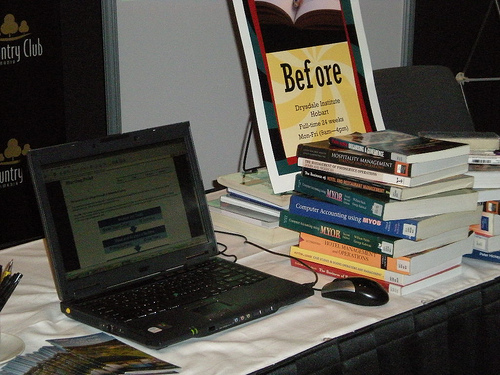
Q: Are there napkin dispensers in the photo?
A: No, there are no napkin dispensers.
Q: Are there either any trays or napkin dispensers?
A: No, there are no napkin dispensers or trays.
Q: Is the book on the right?
A: Yes, the book is on the right of the image.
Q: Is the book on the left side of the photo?
A: No, the book is on the right of the image.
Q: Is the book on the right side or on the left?
A: The book is on the right of the image.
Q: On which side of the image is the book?
A: The book is on the right of the image.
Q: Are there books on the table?
A: Yes, there is a book on the table.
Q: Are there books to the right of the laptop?
A: Yes, there is a book to the right of the laptop.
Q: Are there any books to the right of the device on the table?
A: Yes, there is a book to the right of the laptop.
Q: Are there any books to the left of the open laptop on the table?
A: No, the book is to the right of the laptop.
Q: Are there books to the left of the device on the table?
A: No, the book is to the right of the laptop.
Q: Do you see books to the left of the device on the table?
A: No, the book is to the right of the laptop.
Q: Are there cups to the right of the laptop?
A: No, there is a book to the right of the laptop.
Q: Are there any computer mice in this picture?
A: Yes, there is a computer mouse.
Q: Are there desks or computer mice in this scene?
A: Yes, there is a computer mouse.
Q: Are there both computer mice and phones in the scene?
A: No, there is a computer mouse but no phones.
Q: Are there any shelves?
A: No, there are no shelves.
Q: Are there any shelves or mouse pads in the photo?
A: No, there are no shelves or mouse pads.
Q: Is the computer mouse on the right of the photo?
A: Yes, the computer mouse is on the right of the image.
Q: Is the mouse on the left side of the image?
A: No, the mouse is on the right of the image.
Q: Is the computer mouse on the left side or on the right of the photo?
A: The computer mouse is on the right of the image.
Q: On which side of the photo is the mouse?
A: The mouse is on the right of the image.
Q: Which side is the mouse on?
A: The mouse is on the right of the image.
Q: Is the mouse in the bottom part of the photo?
A: Yes, the mouse is in the bottom of the image.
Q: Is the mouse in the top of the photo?
A: No, the mouse is in the bottom of the image.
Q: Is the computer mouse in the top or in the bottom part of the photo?
A: The computer mouse is in the bottom of the image.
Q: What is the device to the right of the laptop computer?
A: The device is a computer mouse.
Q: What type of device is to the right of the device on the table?
A: The device is a computer mouse.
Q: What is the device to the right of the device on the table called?
A: The device is a computer mouse.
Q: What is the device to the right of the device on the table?
A: The device is a computer mouse.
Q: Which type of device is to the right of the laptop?
A: The device is a computer mouse.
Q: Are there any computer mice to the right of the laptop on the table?
A: Yes, there is a computer mouse to the right of the laptop.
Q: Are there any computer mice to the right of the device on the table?
A: Yes, there is a computer mouse to the right of the laptop.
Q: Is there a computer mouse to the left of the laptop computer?
A: No, the computer mouse is to the right of the laptop computer.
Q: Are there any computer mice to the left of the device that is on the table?
A: No, the computer mouse is to the right of the laptop computer.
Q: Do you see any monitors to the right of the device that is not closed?
A: No, there is a computer mouse to the right of the laptop.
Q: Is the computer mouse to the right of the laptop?
A: Yes, the computer mouse is to the right of the laptop.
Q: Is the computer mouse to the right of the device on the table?
A: Yes, the computer mouse is to the right of the laptop.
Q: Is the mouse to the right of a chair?
A: No, the mouse is to the right of the laptop.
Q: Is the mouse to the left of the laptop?
A: No, the mouse is to the right of the laptop.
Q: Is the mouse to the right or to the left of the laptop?
A: The mouse is to the right of the laptop.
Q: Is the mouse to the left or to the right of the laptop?
A: The mouse is to the right of the laptop.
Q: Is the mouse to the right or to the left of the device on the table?
A: The mouse is to the right of the laptop.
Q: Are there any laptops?
A: Yes, there is a laptop.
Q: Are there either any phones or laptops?
A: Yes, there is a laptop.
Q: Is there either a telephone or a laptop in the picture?
A: Yes, there is a laptop.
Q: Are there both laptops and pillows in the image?
A: No, there is a laptop but no pillows.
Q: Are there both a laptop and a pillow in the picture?
A: No, there is a laptop but no pillows.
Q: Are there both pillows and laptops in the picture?
A: No, there is a laptop but no pillows.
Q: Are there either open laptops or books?
A: Yes, there is an open laptop.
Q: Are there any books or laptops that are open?
A: Yes, the laptop is open.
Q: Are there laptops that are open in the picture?
A: Yes, there is an open laptop.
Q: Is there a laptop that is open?
A: Yes, there is a laptop that is open.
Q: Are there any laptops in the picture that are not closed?
A: Yes, there is a open laptop.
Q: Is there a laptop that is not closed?
A: Yes, there is a open laptop.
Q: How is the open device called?
A: The device is a laptop.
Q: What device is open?
A: The device is a laptop.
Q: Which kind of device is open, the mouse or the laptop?
A: The laptop is open.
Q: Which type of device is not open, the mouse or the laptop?
A: The mouse is not open.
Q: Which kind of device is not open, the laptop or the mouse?
A: The mouse is not open.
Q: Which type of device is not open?
A: The device is a computer mouse.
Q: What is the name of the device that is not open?
A: The device is a computer mouse.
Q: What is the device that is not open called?
A: The device is a computer mouse.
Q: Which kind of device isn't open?
A: The device is a computer mouse.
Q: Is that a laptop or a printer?
A: That is a laptop.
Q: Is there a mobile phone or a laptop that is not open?
A: No, there is a laptop but it is open.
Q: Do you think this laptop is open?
A: Yes, the laptop is open.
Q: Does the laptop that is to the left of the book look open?
A: Yes, the laptop is open.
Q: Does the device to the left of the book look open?
A: Yes, the laptop is open.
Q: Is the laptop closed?
A: No, the laptop is open.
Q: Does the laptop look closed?
A: No, the laptop is open.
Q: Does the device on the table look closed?
A: No, the laptop is open.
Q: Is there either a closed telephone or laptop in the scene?
A: No, there is a laptop but it is open.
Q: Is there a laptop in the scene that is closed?
A: No, there is a laptop but it is open.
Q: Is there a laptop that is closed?
A: No, there is a laptop but it is open.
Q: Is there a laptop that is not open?
A: No, there is a laptop but it is open.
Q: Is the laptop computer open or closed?
A: The laptop computer is open.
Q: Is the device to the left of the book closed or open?
A: The laptop computer is open.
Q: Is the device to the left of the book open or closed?
A: The laptop computer is open.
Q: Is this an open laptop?
A: Yes, this is an open laptop.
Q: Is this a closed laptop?
A: No, this is an open laptop.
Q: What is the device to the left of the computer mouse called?
A: The device is a laptop.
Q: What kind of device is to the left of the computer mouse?
A: The device is a laptop.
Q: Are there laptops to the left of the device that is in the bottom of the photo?
A: Yes, there is a laptop to the left of the mouse.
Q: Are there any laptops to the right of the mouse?
A: No, the laptop is to the left of the mouse.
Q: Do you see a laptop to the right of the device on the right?
A: No, the laptop is to the left of the mouse.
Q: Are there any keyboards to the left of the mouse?
A: No, there is a laptop to the left of the mouse.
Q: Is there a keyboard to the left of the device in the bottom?
A: No, there is a laptop to the left of the mouse.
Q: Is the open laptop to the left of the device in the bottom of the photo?
A: Yes, the laptop is to the left of the mouse.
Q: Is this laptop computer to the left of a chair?
A: No, the laptop computer is to the left of the mouse.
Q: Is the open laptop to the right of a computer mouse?
A: No, the laptop is to the left of a computer mouse.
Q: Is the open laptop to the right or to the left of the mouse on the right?
A: The laptop is to the left of the computer mouse.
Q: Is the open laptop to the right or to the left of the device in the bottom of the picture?
A: The laptop is to the left of the computer mouse.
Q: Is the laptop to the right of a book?
A: No, the laptop is to the left of a book.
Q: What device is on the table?
A: The device is a laptop.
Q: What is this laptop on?
A: The laptop is on the table.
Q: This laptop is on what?
A: The laptop is on the table.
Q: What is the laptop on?
A: The laptop is on the table.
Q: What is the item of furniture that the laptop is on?
A: The piece of furniture is a table.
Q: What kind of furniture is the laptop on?
A: The laptop is on the table.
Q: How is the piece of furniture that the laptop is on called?
A: The piece of furniture is a table.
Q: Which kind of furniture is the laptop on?
A: The laptop is on the table.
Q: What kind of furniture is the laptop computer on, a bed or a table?
A: The laptop computer is on a table.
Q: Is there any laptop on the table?
A: Yes, there is a laptop on the table.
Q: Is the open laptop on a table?
A: Yes, the laptop is on a table.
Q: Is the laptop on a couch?
A: No, the laptop is on a table.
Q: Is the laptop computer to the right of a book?
A: No, the laptop computer is to the left of a book.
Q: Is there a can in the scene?
A: No, there are no cans.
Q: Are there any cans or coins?
A: No, there are no cans or coins.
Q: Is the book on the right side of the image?
A: Yes, the book is on the right of the image.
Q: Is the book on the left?
A: No, the book is on the right of the image.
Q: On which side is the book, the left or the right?
A: The book is on the right of the image.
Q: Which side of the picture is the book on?
A: The book is on the right of the image.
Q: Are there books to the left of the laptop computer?
A: No, the book is to the right of the laptop computer.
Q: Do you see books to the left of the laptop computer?
A: No, the book is to the right of the laptop computer.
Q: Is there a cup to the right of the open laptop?
A: No, there is a book to the right of the laptop computer.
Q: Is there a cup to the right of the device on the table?
A: No, there is a book to the right of the laptop computer.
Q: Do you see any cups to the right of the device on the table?
A: No, there is a book to the right of the laptop computer.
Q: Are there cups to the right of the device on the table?
A: No, there is a book to the right of the laptop computer.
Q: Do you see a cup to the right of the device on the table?
A: No, there is a book to the right of the laptop computer.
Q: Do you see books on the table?
A: Yes, there is a book on the table.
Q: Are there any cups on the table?
A: No, there is a book on the table.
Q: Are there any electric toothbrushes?
A: No, there are no electric toothbrushes.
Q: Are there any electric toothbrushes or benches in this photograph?
A: No, there are no electric toothbrushes or benches.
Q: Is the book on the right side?
A: Yes, the book is on the right of the image.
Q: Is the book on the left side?
A: No, the book is on the right of the image.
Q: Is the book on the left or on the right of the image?
A: The book is on the right of the image.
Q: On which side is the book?
A: The book is on the right of the image.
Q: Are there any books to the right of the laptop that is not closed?
A: Yes, there is a book to the right of the laptop computer.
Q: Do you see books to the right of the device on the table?
A: Yes, there is a book to the right of the laptop computer.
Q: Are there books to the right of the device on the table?
A: Yes, there is a book to the right of the laptop computer.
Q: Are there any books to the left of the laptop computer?
A: No, the book is to the right of the laptop computer.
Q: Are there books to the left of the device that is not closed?
A: No, the book is to the right of the laptop computer.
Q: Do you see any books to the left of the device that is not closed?
A: No, the book is to the right of the laptop computer.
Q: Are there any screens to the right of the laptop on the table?
A: No, there is a book to the right of the laptop.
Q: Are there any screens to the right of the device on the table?
A: No, there is a book to the right of the laptop.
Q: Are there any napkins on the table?
A: No, there is a book on the table.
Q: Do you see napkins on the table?
A: No, there is a book on the table.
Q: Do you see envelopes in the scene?
A: No, there are no envelopes.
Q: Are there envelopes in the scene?
A: No, there are no envelopes.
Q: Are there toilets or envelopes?
A: No, there are no envelopes or toilets.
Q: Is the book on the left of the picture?
A: No, the book is on the right of the image.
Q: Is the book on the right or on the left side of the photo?
A: The book is on the right of the image.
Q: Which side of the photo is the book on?
A: The book is on the right of the image.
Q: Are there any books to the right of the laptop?
A: Yes, there is a book to the right of the laptop.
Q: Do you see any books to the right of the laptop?
A: Yes, there is a book to the right of the laptop.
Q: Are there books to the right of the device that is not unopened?
A: Yes, there is a book to the right of the laptop.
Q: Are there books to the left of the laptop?
A: No, the book is to the right of the laptop.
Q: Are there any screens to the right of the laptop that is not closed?
A: No, there is a book to the right of the laptop.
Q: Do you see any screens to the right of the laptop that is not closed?
A: No, there is a book to the right of the laptop.